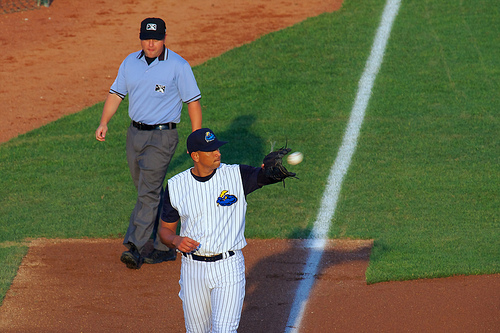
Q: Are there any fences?
A: No, there are no fences.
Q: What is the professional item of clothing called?
A: The clothing item is a uniform.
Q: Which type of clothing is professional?
A: The clothing is a uniform.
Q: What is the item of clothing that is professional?
A: The clothing item is a uniform.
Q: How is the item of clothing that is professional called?
A: The clothing item is a uniform.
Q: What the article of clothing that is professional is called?
A: The clothing item is a uniform.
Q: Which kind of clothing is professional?
A: The clothing is a uniform.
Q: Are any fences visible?
A: No, there are no fences.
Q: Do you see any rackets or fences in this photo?
A: No, there are no fences or rackets.